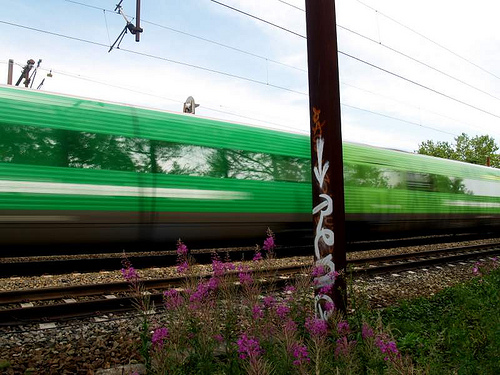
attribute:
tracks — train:
[11, 235, 499, 331]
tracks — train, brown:
[6, 248, 494, 318]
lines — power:
[5, 5, 497, 136]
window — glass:
[154, 138, 224, 178]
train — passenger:
[3, 82, 497, 258]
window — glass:
[228, 150, 273, 181]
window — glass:
[273, 154, 313, 181]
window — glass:
[343, 161, 386, 187]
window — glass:
[375, 165, 411, 193]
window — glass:
[401, 170, 428, 189]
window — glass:
[434, 174, 464, 191]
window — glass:
[469, 180, 494, 195]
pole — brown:
[303, 2, 347, 325]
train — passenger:
[0, 86, 481, 246]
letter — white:
[309, 191, 331, 229]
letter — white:
[311, 226, 334, 259]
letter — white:
[310, 252, 334, 288]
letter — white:
[314, 294, 335, 317]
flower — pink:
[239, 320, 258, 366]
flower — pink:
[302, 308, 331, 341]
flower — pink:
[355, 313, 375, 341]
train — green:
[10, 118, 270, 208]